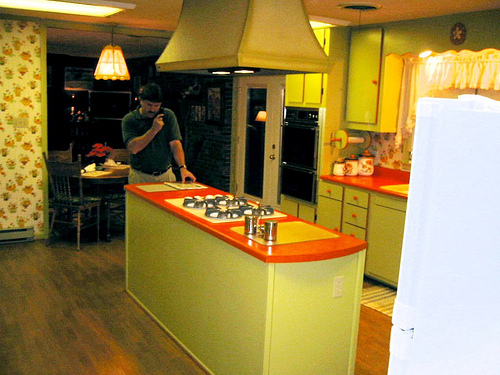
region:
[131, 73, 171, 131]
Man is talking on the phone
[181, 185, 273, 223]
Stovetop has 4 burners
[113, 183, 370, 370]
Stove is on an island in the middle of the kitchen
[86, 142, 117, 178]
Dining room table in background has red flowers on it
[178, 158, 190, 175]
Man is wearing a watch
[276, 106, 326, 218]
Double oven is black and to the right of the man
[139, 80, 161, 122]
Man has black hair and a mustache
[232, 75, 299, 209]
White backdoor is closed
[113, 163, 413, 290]
Counters in the kitchen are orange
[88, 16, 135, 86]
All lights are on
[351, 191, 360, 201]
a red cabinet knob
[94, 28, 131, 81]
a hanging ceiling light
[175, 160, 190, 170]
a man's black wristwatch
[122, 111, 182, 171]
a man's green shirt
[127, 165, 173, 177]
a man's black belt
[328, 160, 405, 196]
part of a red counter top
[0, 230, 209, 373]
brown hardwood floor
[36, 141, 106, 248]
a wooden chair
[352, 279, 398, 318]
part of a white rug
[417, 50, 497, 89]
white curtains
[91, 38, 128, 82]
lamp shade hanging down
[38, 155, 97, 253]
brown kitchen chair on ground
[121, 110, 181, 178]
green polo shirt on man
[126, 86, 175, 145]
man talking on cell phone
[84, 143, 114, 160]
red flowers on table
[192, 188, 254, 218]
gas stove on counter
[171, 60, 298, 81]
bent above stove counter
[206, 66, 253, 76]
lights above stove counter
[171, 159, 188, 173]
watch on wrist of hand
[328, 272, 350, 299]
white electrical outlet on wall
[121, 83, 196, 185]
A man holding a phone.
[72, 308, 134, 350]
Part of the floor.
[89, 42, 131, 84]
A light hanging from the ceiling.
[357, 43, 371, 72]
Part of the green cabnet.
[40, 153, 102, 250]
A brown wooden chair.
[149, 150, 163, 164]
Part of a green shirt.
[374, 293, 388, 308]
Part of the kitchen mat.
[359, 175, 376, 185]
Part of the orange counter.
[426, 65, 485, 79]
Part of the white curtains.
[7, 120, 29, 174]
Part of the wall.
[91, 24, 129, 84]
a light that is on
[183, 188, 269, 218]
four stove top burners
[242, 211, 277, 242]
stainless steel shakers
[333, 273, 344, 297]
a white wall outlet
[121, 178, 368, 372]
a long center island counter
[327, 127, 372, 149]
an empty paper towel holder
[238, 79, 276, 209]
a white door with a large window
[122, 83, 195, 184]
a man talking on a phone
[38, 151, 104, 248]
a chair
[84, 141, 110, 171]
red flowers on a table